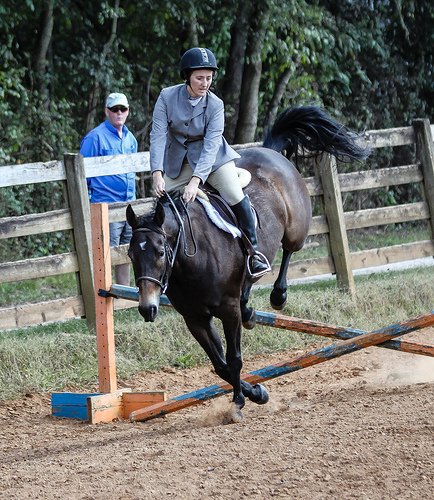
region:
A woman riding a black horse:
[118, 33, 345, 399]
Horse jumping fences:
[64, 173, 426, 409]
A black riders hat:
[171, 46, 221, 90]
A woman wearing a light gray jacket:
[152, 88, 232, 180]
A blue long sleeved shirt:
[73, 118, 138, 201]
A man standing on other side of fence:
[67, 79, 138, 292]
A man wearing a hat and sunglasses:
[82, 89, 136, 270]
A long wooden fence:
[28, 155, 433, 246]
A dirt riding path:
[168, 396, 336, 474]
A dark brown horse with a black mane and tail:
[100, 104, 368, 410]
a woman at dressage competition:
[125, 48, 371, 407]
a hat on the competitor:
[184, 48, 218, 95]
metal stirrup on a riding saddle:
[247, 249, 271, 278]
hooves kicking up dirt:
[211, 383, 281, 425]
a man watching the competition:
[76, 91, 138, 290]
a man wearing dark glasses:
[80, 93, 138, 288]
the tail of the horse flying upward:
[264, 103, 374, 165]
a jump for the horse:
[51, 203, 432, 422]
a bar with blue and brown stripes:
[128, 314, 433, 419]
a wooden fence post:
[63, 152, 94, 329]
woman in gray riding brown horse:
[141, 44, 273, 282]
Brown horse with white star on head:
[112, 100, 371, 426]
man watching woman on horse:
[70, 84, 144, 294]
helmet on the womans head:
[175, 44, 217, 100]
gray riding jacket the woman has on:
[147, 83, 240, 181]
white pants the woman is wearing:
[147, 157, 246, 209]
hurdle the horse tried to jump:
[83, 193, 432, 422]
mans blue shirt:
[73, 126, 139, 203]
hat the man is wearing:
[101, 91, 130, 108]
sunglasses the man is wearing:
[104, 100, 131, 114]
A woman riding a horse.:
[111, 33, 354, 450]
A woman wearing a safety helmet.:
[173, 38, 221, 98]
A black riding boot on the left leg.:
[227, 192, 269, 268]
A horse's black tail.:
[255, 94, 360, 163]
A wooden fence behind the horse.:
[1, 135, 425, 323]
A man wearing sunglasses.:
[99, 86, 130, 129]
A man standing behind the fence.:
[74, 91, 141, 303]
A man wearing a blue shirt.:
[73, 89, 135, 213]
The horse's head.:
[122, 200, 179, 319]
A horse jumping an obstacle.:
[70, 153, 402, 430]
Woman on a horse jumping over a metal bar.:
[51, 47, 431, 423]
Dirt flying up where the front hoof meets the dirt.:
[215, 398, 243, 430]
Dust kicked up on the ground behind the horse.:
[351, 338, 432, 391]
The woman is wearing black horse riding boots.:
[226, 194, 268, 275]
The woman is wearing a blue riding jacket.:
[149, 84, 240, 182]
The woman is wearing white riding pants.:
[159, 162, 242, 204]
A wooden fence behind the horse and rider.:
[0, 117, 433, 327]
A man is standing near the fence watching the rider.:
[81, 92, 141, 284]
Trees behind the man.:
[2, 0, 432, 253]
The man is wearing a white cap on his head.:
[105, 92, 131, 108]